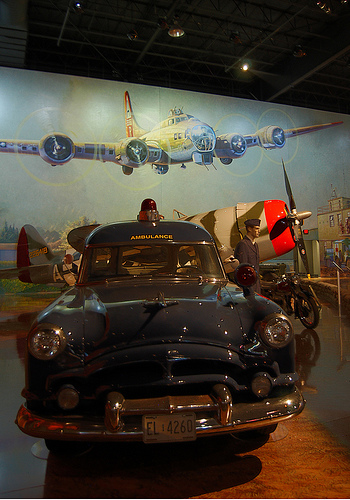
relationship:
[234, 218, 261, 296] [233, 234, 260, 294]
man in uniform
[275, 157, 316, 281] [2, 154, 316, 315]
propellar in airplane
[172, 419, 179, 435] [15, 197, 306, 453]
number in ambulance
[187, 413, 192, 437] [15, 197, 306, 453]
number in ambulance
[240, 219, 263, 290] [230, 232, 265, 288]
man wearing uniform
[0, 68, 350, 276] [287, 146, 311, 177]
painting on wall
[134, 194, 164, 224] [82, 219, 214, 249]
light beneath roof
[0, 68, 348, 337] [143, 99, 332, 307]
painting laying against wall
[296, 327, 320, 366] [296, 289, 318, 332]
shadow caused by wheel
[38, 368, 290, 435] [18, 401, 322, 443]
plate on bumper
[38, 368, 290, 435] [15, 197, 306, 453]
plate on ambulance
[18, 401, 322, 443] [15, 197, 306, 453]
bumper on ambulance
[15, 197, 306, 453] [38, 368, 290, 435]
ambulance with plate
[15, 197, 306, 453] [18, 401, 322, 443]
ambulance with bumper